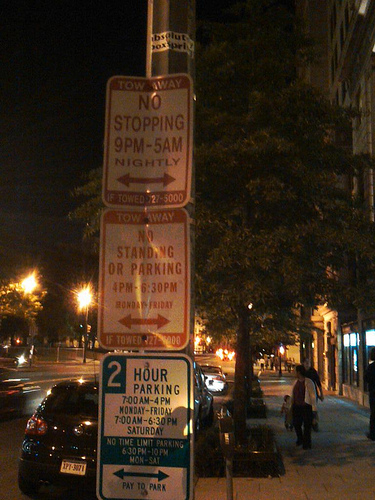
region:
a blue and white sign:
[92, 349, 196, 496]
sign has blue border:
[91, 345, 204, 498]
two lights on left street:
[14, 261, 97, 370]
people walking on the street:
[270, 348, 339, 461]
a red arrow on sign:
[109, 309, 185, 332]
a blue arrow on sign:
[102, 464, 183, 481]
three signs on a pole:
[48, 8, 223, 499]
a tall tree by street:
[203, 86, 323, 491]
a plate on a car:
[46, 459, 94, 476]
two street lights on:
[0, 258, 100, 313]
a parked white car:
[195, 361, 226, 388]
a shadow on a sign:
[136, 353, 193, 474]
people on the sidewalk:
[273, 344, 335, 460]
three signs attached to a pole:
[91, 69, 198, 497]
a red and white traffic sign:
[98, 70, 196, 205]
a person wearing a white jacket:
[288, 365, 315, 404]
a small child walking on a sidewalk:
[280, 390, 295, 426]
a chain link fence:
[19, 342, 83, 361]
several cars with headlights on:
[215, 346, 235, 362]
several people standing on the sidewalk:
[260, 349, 280, 373]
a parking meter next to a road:
[216, 403, 240, 498]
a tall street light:
[77, 280, 93, 364]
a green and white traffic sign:
[94, 352, 199, 498]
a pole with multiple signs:
[56, 2, 226, 498]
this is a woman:
[277, 362, 327, 452]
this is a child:
[274, 385, 294, 439]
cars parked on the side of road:
[2, 327, 228, 493]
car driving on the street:
[3, 358, 52, 419]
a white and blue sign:
[81, 339, 197, 499]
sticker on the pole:
[133, 22, 210, 65]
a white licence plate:
[52, 455, 94, 478]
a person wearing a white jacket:
[290, 365, 317, 450]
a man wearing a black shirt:
[302, 357, 321, 377]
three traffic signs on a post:
[91, 59, 195, 498]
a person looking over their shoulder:
[291, 363, 316, 386]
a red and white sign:
[98, 206, 190, 351]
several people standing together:
[257, 352, 283, 371]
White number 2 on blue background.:
[105, 359, 122, 385]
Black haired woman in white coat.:
[284, 363, 319, 449]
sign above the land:
[67, 58, 225, 219]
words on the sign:
[91, 364, 198, 489]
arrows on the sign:
[95, 454, 183, 488]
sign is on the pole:
[102, 69, 194, 204]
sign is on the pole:
[98, 349, 192, 497]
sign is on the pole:
[97, 203, 191, 351]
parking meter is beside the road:
[216, 402, 236, 497]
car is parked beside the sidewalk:
[19, 380, 102, 498]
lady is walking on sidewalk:
[290, 363, 318, 450]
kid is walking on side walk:
[281, 392, 295, 428]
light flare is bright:
[71, 281, 99, 313]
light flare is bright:
[21, 266, 41, 291]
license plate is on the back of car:
[60, 458, 87, 477]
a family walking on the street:
[271, 354, 334, 460]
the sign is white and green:
[92, 347, 200, 498]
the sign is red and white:
[92, 203, 195, 352]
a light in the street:
[18, 266, 43, 302]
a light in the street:
[73, 283, 98, 313]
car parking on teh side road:
[21, 354, 235, 487]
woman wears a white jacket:
[280, 360, 321, 456]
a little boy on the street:
[278, 388, 295, 430]